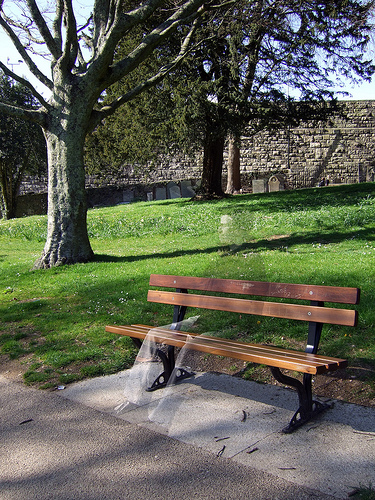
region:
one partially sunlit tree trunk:
[38, 129, 95, 266]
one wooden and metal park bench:
[93, 269, 357, 433]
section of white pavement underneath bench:
[50, 343, 367, 489]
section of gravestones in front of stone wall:
[109, 164, 368, 201]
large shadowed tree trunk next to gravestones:
[110, 138, 226, 202]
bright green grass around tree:
[8, 244, 100, 335]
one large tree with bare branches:
[3, 4, 200, 261]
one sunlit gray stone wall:
[286, 120, 371, 186]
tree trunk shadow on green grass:
[94, 231, 211, 266]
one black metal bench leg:
[263, 367, 336, 435]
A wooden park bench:
[104, 269, 357, 399]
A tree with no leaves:
[12, 0, 131, 258]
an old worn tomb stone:
[268, 175, 284, 190]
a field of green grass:
[258, 201, 366, 227]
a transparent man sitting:
[107, 201, 271, 430]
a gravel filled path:
[47, 439, 151, 488]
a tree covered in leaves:
[138, 87, 256, 192]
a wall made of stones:
[312, 112, 365, 148]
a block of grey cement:
[296, 419, 372, 484]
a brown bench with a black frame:
[116, 270, 364, 421]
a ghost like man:
[116, 184, 279, 457]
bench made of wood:
[102, 235, 358, 443]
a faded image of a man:
[106, 209, 260, 440]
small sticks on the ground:
[211, 410, 262, 467]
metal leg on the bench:
[272, 367, 333, 431]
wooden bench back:
[145, 271, 359, 326]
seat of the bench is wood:
[107, 317, 344, 372]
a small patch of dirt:
[261, 233, 285, 240]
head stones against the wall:
[119, 177, 280, 203]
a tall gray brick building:
[5, 105, 369, 196]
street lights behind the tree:
[1, 56, 26, 70]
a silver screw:
[305, 310, 310, 314]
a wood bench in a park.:
[103, 264, 361, 427]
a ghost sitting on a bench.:
[94, 187, 283, 440]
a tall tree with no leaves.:
[0, 0, 224, 261]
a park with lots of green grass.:
[0, 185, 372, 397]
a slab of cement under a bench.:
[47, 359, 373, 494]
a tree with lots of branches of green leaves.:
[81, 0, 373, 215]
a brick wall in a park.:
[0, 99, 371, 209]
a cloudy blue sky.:
[0, 0, 373, 107]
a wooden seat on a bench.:
[103, 318, 347, 379]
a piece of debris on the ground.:
[214, 444, 233, 456]